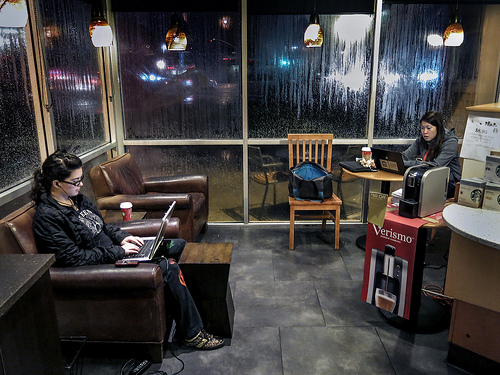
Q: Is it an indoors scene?
A: Yes, it is indoors.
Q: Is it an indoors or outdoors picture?
A: It is indoors.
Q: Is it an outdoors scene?
A: No, it is indoors.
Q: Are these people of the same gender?
A: Yes, all the people are female.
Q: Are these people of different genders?
A: No, all the people are female.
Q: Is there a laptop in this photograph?
A: Yes, there is a laptop.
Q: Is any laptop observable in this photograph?
A: Yes, there is a laptop.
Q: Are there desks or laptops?
A: Yes, there is a laptop.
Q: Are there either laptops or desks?
A: Yes, there is a laptop.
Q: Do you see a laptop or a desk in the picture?
A: Yes, there is a laptop.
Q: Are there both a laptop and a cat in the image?
A: No, there is a laptop but no cats.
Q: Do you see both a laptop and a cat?
A: No, there is a laptop but no cats.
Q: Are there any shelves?
A: No, there are no shelves.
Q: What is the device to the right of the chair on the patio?
A: The device is a laptop.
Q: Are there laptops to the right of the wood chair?
A: Yes, there is a laptop to the right of the chair.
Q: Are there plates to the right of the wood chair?
A: No, there is a laptop to the right of the chair.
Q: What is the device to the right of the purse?
A: The device is a laptop.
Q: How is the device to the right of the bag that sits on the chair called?
A: The device is a laptop.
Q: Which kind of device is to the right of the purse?
A: The device is a laptop.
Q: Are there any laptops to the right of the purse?
A: Yes, there is a laptop to the right of the purse.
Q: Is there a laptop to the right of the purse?
A: Yes, there is a laptop to the right of the purse.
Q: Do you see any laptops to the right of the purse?
A: Yes, there is a laptop to the right of the purse.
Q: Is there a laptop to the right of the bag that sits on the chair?
A: Yes, there is a laptop to the right of the purse.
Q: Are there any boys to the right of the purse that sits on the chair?
A: No, there is a laptop to the right of the purse.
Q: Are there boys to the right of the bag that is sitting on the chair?
A: No, there is a laptop to the right of the purse.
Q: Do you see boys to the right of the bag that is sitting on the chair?
A: No, there is a laptop to the right of the purse.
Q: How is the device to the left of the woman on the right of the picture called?
A: The device is a laptop.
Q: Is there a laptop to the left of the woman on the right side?
A: Yes, there is a laptop to the left of the woman.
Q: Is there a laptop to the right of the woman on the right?
A: No, the laptop is to the left of the woman.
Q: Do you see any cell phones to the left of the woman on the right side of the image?
A: No, there is a laptop to the left of the woman.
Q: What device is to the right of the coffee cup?
A: The device is a laptop.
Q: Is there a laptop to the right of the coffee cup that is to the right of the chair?
A: Yes, there is a laptop to the right of the coffee cup.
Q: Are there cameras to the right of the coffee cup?
A: No, there is a laptop to the right of the coffee cup.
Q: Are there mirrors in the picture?
A: No, there are no mirrors.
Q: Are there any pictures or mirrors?
A: No, there are no mirrors or pictures.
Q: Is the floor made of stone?
A: Yes, the floor is made of stone.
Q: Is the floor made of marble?
A: No, the floor is made of stone.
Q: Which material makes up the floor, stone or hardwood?
A: The floor is made of stone.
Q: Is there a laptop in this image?
A: Yes, there is a laptop.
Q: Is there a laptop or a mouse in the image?
A: Yes, there is a laptop.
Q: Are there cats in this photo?
A: No, there are no cats.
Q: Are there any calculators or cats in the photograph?
A: No, there are no cats or calculators.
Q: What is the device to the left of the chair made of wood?
A: The device is a laptop.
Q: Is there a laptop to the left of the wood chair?
A: Yes, there is a laptop to the left of the chair.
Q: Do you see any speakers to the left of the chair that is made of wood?
A: No, there is a laptop to the left of the chair.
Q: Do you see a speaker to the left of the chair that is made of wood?
A: No, there is a laptop to the left of the chair.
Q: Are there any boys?
A: No, there are no boys.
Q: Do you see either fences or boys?
A: No, there are no boys or fences.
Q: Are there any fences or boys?
A: No, there are no boys or fences.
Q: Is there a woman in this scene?
A: Yes, there is a woman.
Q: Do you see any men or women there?
A: Yes, there is a woman.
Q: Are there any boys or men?
A: No, there are no boys or men.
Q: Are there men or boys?
A: No, there are no boys or men.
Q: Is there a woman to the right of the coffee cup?
A: Yes, there is a woman to the right of the coffee cup.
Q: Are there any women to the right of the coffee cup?
A: Yes, there is a woman to the right of the coffee cup.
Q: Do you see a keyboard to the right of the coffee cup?
A: No, there is a woman to the right of the coffee cup.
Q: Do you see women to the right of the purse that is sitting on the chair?
A: Yes, there is a woman to the right of the purse.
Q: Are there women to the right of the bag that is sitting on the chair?
A: Yes, there is a woman to the right of the purse.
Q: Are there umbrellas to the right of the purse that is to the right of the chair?
A: No, there is a woman to the right of the purse.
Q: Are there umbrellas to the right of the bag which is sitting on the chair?
A: No, there is a woman to the right of the purse.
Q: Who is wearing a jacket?
A: The woman is wearing a jacket.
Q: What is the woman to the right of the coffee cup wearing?
A: The woman is wearing a jacket.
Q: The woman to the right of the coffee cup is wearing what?
A: The woman is wearing a jacket.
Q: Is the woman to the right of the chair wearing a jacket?
A: Yes, the woman is wearing a jacket.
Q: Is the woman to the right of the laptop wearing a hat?
A: No, the woman is wearing a jacket.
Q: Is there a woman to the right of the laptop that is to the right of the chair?
A: Yes, there is a woman to the right of the laptop.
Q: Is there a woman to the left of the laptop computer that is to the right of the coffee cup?
A: No, the woman is to the right of the laptop.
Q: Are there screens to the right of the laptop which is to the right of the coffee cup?
A: No, there is a woman to the right of the laptop computer.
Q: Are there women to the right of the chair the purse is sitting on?
A: Yes, there is a woman to the right of the chair.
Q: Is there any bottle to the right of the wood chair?
A: No, there is a woman to the right of the chair.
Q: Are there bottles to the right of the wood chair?
A: No, there is a woman to the right of the chair.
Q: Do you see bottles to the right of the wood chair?
A: No, there is a woman to the right of the chair.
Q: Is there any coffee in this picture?
A: Yes, there is coffee.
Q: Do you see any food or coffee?
A: Yes, there is coffee.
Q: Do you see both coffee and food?
A: No, there is coffee but no food.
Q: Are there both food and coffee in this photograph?
A: No, there is coffee but no food.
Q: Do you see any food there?
A: No, there is no food.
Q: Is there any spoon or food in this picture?
A: No, there are no food or spoons.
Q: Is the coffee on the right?
A: Yes, the coffee is on the right of the image.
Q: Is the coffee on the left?
A: No, the coffee is on the right of the image.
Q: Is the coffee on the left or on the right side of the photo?
A: The coffee is on the right of the image.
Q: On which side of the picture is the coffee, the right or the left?
A: The coffee is on the right of the image.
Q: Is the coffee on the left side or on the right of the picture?
A: The coffee is on the right of the image.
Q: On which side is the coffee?
A: The coffee is on the right of the image.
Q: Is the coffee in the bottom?
A: Yes, the coffee is in the bottom of the image.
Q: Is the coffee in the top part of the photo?
A: No, the coffee is in the bottom of the image.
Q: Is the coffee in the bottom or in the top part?
A: The coffee is in the bottom of the image.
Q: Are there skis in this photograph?
A: No, there are no skis.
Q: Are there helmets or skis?
A: No, there are no skis or helmets.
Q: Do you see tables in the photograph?
A: Yes, there is a table.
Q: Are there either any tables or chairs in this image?
A: Yes, there is a table.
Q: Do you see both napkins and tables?
A: No, there is a table but no napkins.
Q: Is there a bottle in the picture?
A: No, there are no bottles.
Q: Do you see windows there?
A: Yes, there are windows.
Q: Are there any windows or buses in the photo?
A: Yes, there are windows.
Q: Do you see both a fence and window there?
A: No, there are windows but no fences.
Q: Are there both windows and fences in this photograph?
A: No, there are windows but no fences.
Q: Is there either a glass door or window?
A: Yes, there are glass windows.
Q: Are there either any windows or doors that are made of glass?
A: Yes, the windows are made of glass.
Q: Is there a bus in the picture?
A: No, there are no buses.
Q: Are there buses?
A: No, there are no buses.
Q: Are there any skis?
A: No, there are no skis.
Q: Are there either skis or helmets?
A: No, there are no skis or helmets.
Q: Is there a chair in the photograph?
A: Yes, there is a chair.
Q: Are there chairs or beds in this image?
A: Yes, there is a chair.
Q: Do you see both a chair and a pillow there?
A: No, there is a chair but no pillows.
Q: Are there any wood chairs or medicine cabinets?
A: Yes, there is a wood chair.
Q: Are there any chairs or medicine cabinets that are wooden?
A: Yes, the chair is wooden.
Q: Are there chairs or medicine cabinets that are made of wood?
A: Yes, the chair is made of wood.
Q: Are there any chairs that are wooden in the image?
A: Yes, there is a wood chair.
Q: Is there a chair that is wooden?
A: Yes, there is a chair that is wooden.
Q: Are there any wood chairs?
A: Yes, there is a chair that is made of wood.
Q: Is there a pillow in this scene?
A: No, there are no pillows.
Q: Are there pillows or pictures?
A: No, there are no pillows or pictures.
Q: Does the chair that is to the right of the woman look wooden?
A: Yes, the chair is wooden.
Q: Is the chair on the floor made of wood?
A: Yes, the chair is made of wood.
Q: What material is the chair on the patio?
A: The chair is made of wood.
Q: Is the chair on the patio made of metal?
A: No, the chair is made of wood.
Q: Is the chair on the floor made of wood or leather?
A: The chair is made of wood.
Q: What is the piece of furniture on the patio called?
A: The piece of furniture is a chair.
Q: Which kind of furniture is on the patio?
A: The piece of furniture is a chair.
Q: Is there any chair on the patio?
A: Yes, there is a chair on the patio.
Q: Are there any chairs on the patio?
A: Yes, there is a chair on the patio.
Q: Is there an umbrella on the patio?
A: No, there is a chair on the patio.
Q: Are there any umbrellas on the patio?
A: No, there is a chair on the patio.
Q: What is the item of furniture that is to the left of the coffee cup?
A: The piece of furniture is a chair.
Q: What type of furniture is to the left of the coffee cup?
A: The piece of furniture is a chair.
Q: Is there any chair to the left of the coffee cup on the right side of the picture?
A: Yes, there is a chair to the left of the coffee cup.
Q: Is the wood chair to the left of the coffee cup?
A: Yes, the chair is to the left of the coffee cup.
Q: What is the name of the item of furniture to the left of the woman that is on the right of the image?
A: The piece of furniture is a chair.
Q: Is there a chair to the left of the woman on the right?
A: Yes, there is a chair to the left of the woman.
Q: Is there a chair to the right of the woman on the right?
A: No, the chair is to the left of the woman.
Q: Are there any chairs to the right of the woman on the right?
A: No, the chair is to the left of the woman.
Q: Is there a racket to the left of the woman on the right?
A: No, there is a chair to the left of the woman.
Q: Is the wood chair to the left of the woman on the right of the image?
A: Yes, the chair is to the left of the woman.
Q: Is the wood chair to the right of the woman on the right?
A: No, the chair is to the left of the woman.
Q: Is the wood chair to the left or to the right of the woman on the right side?
A: The chair is to the left of the woman.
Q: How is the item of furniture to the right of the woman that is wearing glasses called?
A: The piece of furniture is a chair.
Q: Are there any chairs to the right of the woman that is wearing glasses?
A: Yes, there is a chair to the right of the woman.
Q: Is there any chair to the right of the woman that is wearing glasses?
A: Yes, there is a chair to the right of the woman.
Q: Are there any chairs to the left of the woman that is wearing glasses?
A: No, the chair is to the right of the woman.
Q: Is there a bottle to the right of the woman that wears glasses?
A: No, there is a chair to the right of the woman.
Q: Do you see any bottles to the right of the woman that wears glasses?
A: No, there is a chair to the right of the woman.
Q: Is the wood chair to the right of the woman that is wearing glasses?
A: Yes, the chair is to the right of the woman.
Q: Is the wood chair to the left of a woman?
A: No, the chair is to the right of a woman.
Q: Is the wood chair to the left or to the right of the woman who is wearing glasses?
A: The chair is to the right of the woman.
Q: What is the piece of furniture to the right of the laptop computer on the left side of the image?
A: The piece of furniture is a chair.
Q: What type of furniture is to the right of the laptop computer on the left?
A: The piece of furniture is a chair.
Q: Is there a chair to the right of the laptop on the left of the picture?
A: Yes, there is a chair to the right of the laptop computer.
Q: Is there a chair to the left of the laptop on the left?
A: No, the chair is to the right of the laptop.